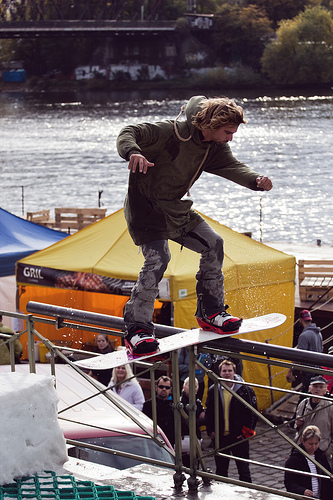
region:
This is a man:
[120, 118, 144, 130]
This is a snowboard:
[72, 339, 201, 399]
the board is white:
[97, 333, 133, 381]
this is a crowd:
[103, 383, 238, 477]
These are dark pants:
[84, 255, 138, 294]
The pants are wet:
[129, 284, 158, 333]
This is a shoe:
[108, 330, 164, 377]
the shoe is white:
[133, 324, 183, 383]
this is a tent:
[88, 262, 112, 315]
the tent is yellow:
[67, 262, 91, 280]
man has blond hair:
[181, 96, 262, 150]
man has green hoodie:
[124, 104, 189, 229]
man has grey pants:
[142, 218, 210, 329]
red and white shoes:
[127, 310, 237, 351]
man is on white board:
[97, 312, 305, 381]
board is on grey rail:
[43, 316, 317, 410]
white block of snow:
[5, 370, 63, 499]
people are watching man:
[121, 335, 318, 483]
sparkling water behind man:
[258, 78, 309, 220]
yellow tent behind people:
[51, 183, 287, 448]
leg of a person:
[115, 214, 174, 349]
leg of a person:
[175, 205, 243, 338]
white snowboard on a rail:
[64, 309, 289, 385]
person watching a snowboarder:
[204, 355, 256, 477]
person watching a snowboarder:
[181, 372, 206, 438]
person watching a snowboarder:
[137, 370, 187, 449]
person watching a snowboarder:
[103, 355, 144, 417]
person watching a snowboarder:
[94, 331, 114, 358]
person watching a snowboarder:
[293, 372, 331, 456]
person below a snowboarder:
[289, 298, 324, 353]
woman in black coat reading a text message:
[277, 421, 332, 496]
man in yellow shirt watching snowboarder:
[202, 358, 261, 484]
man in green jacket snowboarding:
[65, 92, 290, 375]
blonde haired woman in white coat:
[105, 360, 145, 411]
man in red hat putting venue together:
[282, 306, 326, 395]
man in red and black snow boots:
[115, 91, 276, 361]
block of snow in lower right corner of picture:
[1, 366, 70, 490]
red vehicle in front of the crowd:
[2, 359, 178, 481]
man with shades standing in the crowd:
[140, 375, 186, 443]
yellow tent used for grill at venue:
[11, 194, 299, 430]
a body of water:
[32, 62, 325, 212]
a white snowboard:
[41, 304, 328, 385]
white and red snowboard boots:
[110, 297, 262, 367]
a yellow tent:
[23, 196, 299, 431]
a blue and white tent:
[3, 191, 74, 323]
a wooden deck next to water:
[32, 196, 331, 323]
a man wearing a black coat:
[198, 349, 288, 498]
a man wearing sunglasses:
[145, 361, 193, 415]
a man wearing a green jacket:
[106, 82, 265, 245]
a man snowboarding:
[107, 84, 290, 388]